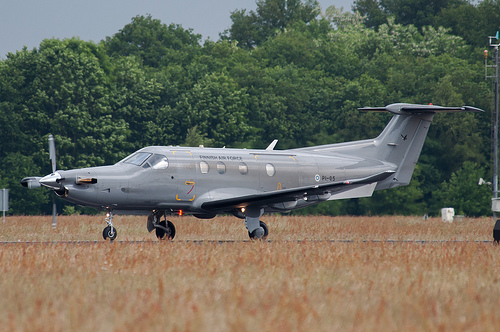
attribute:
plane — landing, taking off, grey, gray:
[26, 107, 425, 218]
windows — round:
[125, 149, 189, 179]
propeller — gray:
[33, 134, 83, 207]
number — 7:
[150, 167, 198, 213]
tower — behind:
[456, 23, 499, 217]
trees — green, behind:
[100, 17, 490, 103]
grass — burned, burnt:
[59, 253, 441, 329]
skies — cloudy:
[16, 3, 272, 42]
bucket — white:
[417, 194, 496, 245]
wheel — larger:
[229, 218, 281, 251]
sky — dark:
[14, 9, 283, 64]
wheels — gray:
[102, 203, 322, 271]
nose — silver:
[35, 156, 68, 208]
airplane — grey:
[40, 110, 484, 301]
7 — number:
[164, 168, 210, 208]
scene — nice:
[25, 10, 429, 310]